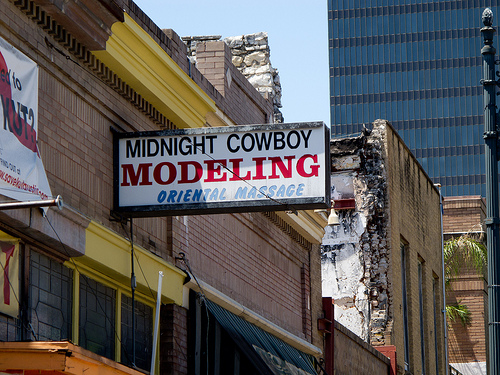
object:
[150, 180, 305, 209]
writing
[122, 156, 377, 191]
writing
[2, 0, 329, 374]
building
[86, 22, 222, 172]
wall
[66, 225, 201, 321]
wall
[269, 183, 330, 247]
wall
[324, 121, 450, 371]
building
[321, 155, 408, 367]
wall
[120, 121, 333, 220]
sign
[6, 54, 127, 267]
wall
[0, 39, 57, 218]
banner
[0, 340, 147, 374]
roof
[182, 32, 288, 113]
brick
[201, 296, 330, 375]
awning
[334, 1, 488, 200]
high rise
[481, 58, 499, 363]
pole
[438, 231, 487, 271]
tree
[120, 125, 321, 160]
writing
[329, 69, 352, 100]
window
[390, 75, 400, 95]
window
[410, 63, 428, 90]
window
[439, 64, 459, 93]
window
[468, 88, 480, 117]
window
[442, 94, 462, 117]
window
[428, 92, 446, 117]
window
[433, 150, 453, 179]
window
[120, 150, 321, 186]
letters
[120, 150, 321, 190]
word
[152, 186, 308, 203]
letters